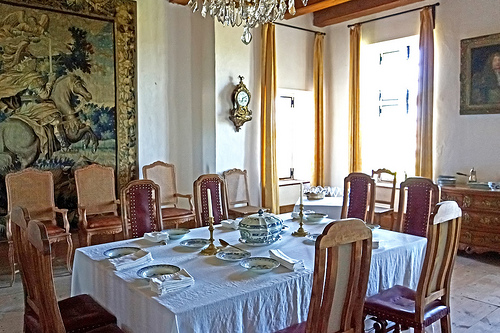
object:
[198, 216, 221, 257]
candle holder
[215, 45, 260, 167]
wall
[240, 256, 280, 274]
plate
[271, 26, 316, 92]
curtain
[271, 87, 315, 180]
window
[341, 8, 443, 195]
shades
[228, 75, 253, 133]
clock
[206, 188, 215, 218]
candles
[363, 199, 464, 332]
chair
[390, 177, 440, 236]
chair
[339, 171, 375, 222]
chair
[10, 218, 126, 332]
chair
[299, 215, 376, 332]
chair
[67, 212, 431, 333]
table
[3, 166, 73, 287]
chair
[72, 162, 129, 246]
chair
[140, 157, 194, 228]
chair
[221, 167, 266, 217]
chair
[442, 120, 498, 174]
wall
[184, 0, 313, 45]
chandelier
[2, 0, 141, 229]
art piece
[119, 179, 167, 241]
chairs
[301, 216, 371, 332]
chair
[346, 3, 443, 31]
rod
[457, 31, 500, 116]
portrait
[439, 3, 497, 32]
wall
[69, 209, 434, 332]
tablecloth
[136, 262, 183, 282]
bowl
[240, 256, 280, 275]
bowl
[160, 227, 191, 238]
bowl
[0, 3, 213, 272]
wall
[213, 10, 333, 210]
wall